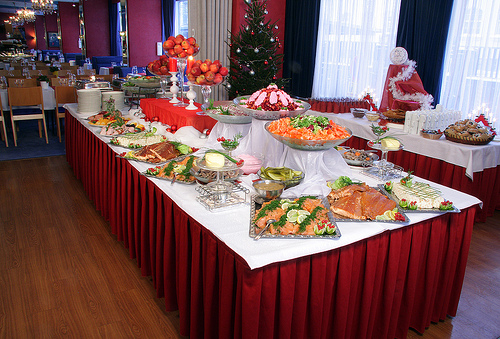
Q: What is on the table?
A: Food.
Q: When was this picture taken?
A: Christmas party.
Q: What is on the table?
A: Food.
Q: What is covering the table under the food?
A: Tablecloth.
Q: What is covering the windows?
A: Curtains.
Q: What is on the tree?
A: Glass balls.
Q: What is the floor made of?
A: Hardwood.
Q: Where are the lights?
A: Ceiling.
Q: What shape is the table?
A: Rectangle.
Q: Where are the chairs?
A: Around the tables.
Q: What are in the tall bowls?
A: Apples.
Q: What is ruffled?
A: Tablecloth.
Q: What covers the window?
A: Curtains.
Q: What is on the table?
A: Food.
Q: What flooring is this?
A: Wood.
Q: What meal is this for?
A: Dinner.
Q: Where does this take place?
A: In a house.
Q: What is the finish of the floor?
A: Smooth.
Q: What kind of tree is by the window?
A: Christmas tree.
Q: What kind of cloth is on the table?
A: White.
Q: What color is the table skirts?
A: Red.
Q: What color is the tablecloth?
A: White.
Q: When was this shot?
A: Daytime.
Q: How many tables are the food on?
A: 2.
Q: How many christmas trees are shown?
A: 1.